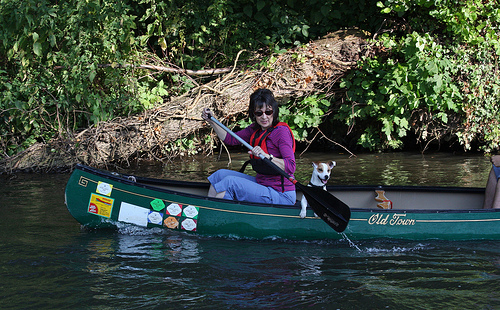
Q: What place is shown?
A: It is a river.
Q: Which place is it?
A: It is a river.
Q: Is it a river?
A: Yes, it is a river.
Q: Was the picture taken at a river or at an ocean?
A: It was taken at a river.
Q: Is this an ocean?
A: No, it is a river.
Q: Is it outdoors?
A: Yes, it is outdoors.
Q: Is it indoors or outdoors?
A: It is outdoors.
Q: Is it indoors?
A: No, it is outdoors.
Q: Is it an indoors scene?
A: No, it is outdoors.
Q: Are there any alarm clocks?
A: No, there are no alarm clocks.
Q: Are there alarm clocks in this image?
A: No, there are no alarm clocks.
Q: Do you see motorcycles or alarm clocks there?
A: No, there are no alarm clocks or motorcycles.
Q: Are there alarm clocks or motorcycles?
A: No, there are no alarm clocks or motorcycles.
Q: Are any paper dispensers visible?
A: No, there are no paper dispensers.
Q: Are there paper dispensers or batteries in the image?
A: No, there are no paper dispensers or batteries.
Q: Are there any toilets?
A: No, there are no toilets.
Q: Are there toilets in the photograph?
A: No, there are no toilets.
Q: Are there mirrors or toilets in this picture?
A: No, there are no toilets or mirrors.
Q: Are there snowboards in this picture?
A: No, there are no snowboards.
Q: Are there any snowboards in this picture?
A: No, there are no snowboards.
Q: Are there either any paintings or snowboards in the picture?
A: No, there are no snowboards or paintings.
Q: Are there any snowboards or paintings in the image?
A: No, there are no snowboards or paintings.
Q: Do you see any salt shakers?
A: No, there are no salt shakers.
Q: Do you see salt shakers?
A: No, there are no salt shakers.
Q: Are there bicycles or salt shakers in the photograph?
A: No, there are no salt shakers or bicycles.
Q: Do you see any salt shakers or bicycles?
A: No, there are no salt shakers or bicycles.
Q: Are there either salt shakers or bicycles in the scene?
A: No, there are no salt shakers or bicycles.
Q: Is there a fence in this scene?
A: No, there are no fences.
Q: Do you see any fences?
A: No, there are no fences.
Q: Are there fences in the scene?
A: No, there are no fences.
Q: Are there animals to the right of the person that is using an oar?
A: Yes, there is an animal to the right of the person.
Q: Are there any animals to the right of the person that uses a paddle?
A: Yes, there is an animal to the right of the person.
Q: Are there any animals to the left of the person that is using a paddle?
A: No, the animal is to the right of the person.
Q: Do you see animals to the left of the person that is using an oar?
A: No, the animal is to the right of the person.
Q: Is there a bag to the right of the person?
A: No, there is an animal to the right of the person.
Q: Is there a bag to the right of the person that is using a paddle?
A: No, there is an animal to the right of the person.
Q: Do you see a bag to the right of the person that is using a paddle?
A: No, there is an animal to the right of the person.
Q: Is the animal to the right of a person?
A: Yes, the animal is to the right of a person.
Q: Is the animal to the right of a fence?
A: No, the animal is to the right of a person.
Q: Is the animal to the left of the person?
A: No, the animal is to the right of the person.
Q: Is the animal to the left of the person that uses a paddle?
A: No, the animal is to the right of the person.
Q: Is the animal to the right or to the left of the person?
A: The animal is to the right of the person.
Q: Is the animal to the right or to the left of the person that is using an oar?
A: The animal is to the right of the person.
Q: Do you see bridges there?
A: No, there are no bridges.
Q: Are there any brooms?
A: No, there are no brooms.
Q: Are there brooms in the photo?
A: No, there are no brooms.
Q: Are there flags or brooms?
A: No, there are no brooms or flags.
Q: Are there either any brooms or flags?
A: No, there are no brooms or flags.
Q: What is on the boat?
A: The sticker is on the boat.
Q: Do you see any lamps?
A: No, there are no lamps.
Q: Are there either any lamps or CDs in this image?
A: No, there are no lamps or cds.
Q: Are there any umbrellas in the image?
A: No, there are no umbrellas.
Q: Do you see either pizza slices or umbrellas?
A: No, there are no umbrellas or pizza slices.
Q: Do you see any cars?
A: No, there are no cars.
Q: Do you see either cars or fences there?
A: No, there are no cars or fences.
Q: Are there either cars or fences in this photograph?
A: No, there are no cars or fences.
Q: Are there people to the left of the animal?
A: Yes, there is a person to the left of the animal.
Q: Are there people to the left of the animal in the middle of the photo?
A: Yes, there is a person to the left of the animal.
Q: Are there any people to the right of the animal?
A: No, the person is to the left of the animal.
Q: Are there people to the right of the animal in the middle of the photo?
A: No, the person is to the left of the animal.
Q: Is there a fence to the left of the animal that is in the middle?
A: No, there is a person to the left of the animal.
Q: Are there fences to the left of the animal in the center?
A: No, there is a person to the left of the animal.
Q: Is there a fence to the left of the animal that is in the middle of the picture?
A: No, there is a person to the left of the animal.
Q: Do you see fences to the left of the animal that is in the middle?
A: No, there is a person to the left of the animal.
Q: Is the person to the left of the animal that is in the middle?
A: Yes, the person is to the left of the animal.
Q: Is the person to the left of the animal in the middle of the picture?
A: Yes, the person is to the left of the animal.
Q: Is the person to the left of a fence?
A: No, the person is to the left of the animal.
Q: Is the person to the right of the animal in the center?
A: No, the person is to the left of the animal.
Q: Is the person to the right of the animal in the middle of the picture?
A: No, the person is to the left of the animal.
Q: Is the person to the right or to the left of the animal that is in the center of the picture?
A: The person is to the left of the animal.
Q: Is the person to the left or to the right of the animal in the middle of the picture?
A: The person is to the left of the animal.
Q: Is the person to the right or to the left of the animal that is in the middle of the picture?
A: The person is to the left of the animal.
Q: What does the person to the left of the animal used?
A: The person uses an oar.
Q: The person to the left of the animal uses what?
A: The person uses an oar.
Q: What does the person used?
A: The person uses an oar.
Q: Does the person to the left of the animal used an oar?
A: Yes, the person uses an oar.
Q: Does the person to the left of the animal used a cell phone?
A: No, the person uses an oar.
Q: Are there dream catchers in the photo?
A: No, there are no dream catchers.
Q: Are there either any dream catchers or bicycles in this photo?
A: No, there are no dream catchers or bicycles.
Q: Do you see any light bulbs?
A: No, there are no light bulbs.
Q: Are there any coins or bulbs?
A: No, there are no bulbs or coins.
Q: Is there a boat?
A: Yes, there is a boat.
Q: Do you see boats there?
A: Yes, there is a boat.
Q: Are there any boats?
A: Yes, there is a boat.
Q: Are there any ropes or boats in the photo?
A: Yes, there is a boat.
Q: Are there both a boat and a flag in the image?
A: No, there is a boat but no flags.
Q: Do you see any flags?
A: No, there are no flags.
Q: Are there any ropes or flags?
A: No, there are no flags or ropes.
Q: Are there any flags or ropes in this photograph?
A: No, there are no flags or ropes.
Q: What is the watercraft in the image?
A: The watercraft is a boat.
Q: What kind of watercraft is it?
A: The watercraft is a boat.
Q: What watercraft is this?
A: This is a boat.